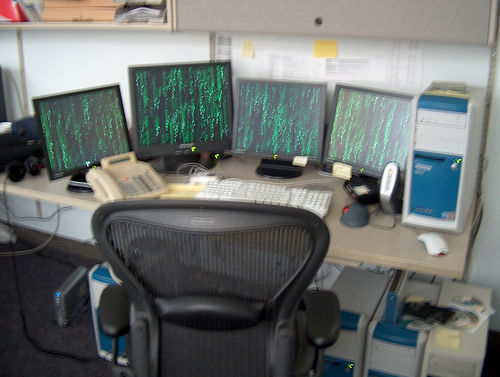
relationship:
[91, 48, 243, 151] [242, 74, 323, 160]
monitor on desk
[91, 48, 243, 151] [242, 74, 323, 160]
comptuer in desk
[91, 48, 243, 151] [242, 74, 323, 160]
computer in desk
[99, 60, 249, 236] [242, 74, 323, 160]
computer on desk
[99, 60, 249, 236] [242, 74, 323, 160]
computer in desk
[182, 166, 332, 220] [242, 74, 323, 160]
keybaord in desk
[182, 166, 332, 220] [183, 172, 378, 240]
keyboard on desk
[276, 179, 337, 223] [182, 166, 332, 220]
key on keyboard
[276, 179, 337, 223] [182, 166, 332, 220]
key in keyboard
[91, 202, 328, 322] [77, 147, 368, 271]
chair in office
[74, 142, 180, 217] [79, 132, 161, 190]
phone in desk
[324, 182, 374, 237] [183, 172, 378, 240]
mouse on desk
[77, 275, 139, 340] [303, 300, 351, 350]
armrest on chair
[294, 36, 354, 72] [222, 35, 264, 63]
paper on wall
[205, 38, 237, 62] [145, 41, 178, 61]
white comptuer tower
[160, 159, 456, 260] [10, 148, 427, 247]
surface of desk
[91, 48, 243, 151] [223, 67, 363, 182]
monitor on desk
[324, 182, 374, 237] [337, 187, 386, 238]
mouse on desk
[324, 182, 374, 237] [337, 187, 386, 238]
mouse in desk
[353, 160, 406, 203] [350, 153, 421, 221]
modem in desk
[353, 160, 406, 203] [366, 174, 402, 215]
modem in light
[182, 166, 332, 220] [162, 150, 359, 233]
keyboard in desk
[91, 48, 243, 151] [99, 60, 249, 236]
green screen computer